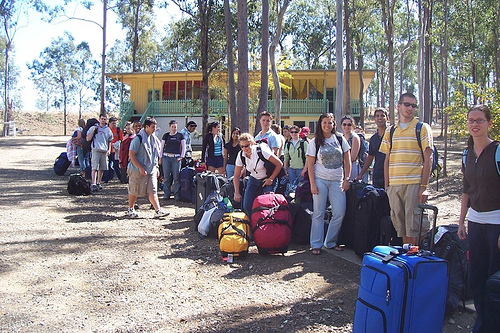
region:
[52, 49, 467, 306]
line of campers outside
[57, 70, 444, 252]
group of people standing outside cabin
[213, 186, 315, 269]
red and yellow duffel bags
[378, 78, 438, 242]
man in yellow striped shirt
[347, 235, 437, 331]
large blue roller bag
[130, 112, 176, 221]
man with sweatshirt draped around neck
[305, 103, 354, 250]
woman in t-shirt and jeans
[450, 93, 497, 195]
woman wearing glasses and black vest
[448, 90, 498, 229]
woman wearing black vest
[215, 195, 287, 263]
yellow and red duffel bags with black straps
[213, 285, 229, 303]
part of a road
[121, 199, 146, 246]
edge of a road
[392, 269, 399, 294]
side of a bag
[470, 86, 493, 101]
part of a tree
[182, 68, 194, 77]
part of a building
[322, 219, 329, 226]
part of a jeans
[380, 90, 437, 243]
A man in a yellow striped shirt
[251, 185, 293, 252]
A large red duffel bag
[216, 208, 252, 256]
A small yellow duffel bag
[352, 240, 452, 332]
A large blue suit case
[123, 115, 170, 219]
A man in tan shorts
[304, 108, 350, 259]
A woman in a white t shirt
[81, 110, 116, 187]
A man in a gray hoodie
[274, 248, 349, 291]
A man's shadow on the ground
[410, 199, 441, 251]
A handle on the suit case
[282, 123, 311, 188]
A man in a green shirt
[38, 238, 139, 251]
shadow cast on the ground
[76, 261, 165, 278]
gravel on the ground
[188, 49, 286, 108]
tall thin trunks on trees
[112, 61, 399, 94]
large yellow house behind people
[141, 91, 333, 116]
green railing on front porch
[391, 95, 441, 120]
glasses on man's face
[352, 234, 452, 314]
blue and black suitcase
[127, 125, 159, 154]
black strap around man's back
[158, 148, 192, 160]
white belts in loop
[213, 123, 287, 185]
woman stooped over suitcase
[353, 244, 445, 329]
large suitcase is blue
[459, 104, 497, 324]
girl wearing denim jeans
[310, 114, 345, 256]
girl wearing denim jeans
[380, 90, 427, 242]
boy wearing tan shorts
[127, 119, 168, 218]
boy wearing tan shorts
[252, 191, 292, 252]
duffle bag is red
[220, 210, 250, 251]
duffle bag is orange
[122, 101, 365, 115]
railing is painted green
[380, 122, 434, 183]
shirt has yellow stripes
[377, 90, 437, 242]
boy wearing yellow shirt